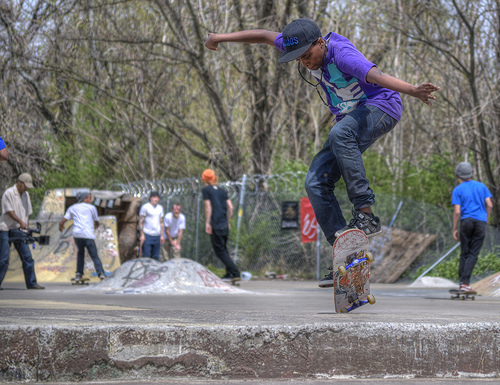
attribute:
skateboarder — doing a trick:
[199, 16, 437, 288]